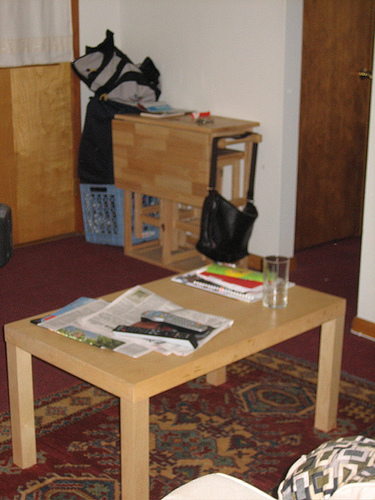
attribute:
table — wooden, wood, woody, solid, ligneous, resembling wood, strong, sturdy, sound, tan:
[2, 261, 350, 499]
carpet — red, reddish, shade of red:
[0, 230, 374, 430]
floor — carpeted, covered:
[2, 229, 374, 499]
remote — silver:
[136, 307, 211, 338]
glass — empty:
[260, 249, 294, 313]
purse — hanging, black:
[195, 127, 262, 267]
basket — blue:
[78, 178, 160, 250]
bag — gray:
[70, 24, 165, 111]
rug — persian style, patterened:
[2, 347, 375, 499]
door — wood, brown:
[295, 1, 372, 255]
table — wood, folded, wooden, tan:
[108, 105, 266, 277]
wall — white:
[117, 2, 305, 269]